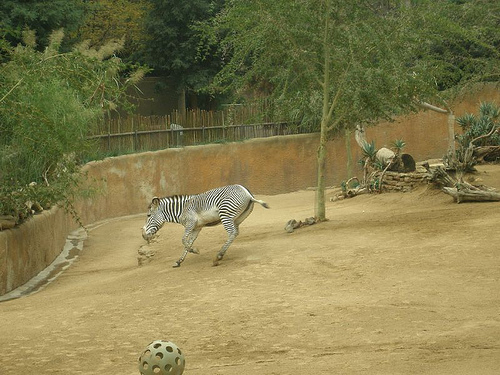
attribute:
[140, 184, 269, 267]
zebra — running, bending, here, black, white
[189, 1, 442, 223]
tree — here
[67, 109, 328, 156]
fence — here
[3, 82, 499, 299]
wall — clay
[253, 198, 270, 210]
tail — here, short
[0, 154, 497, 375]
ground — smooth, here, brown, sand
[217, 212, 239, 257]
leg — here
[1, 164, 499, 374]
dirt — brown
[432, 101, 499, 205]
tree — down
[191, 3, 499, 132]
leaves — green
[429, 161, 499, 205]
wood — here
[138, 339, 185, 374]
helmet — here, white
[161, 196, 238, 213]
stripes — white, black